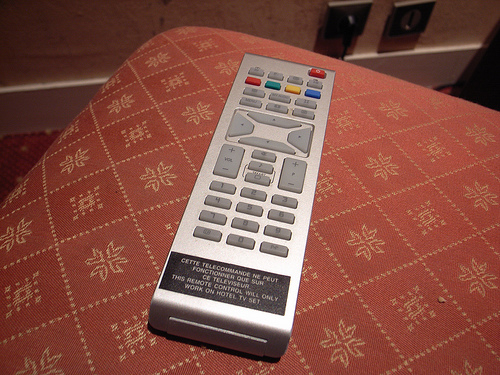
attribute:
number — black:
[242, 189, 269, 202]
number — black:
[199, 206, 227, 226]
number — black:
[235, 199, 264, 217]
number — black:
[248, 77, 322, 187]